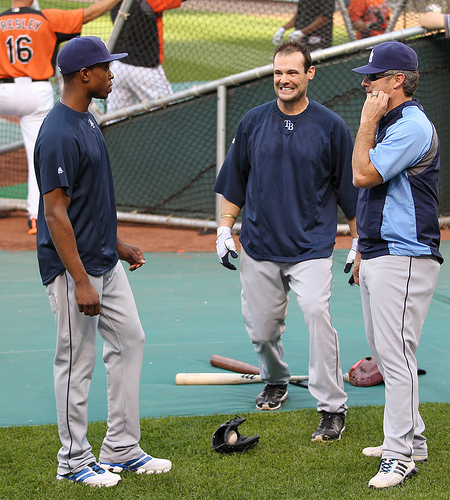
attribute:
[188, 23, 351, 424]
man — smiling, standing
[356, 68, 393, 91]
sunglasses — black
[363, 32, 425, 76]
cap — blue, baseball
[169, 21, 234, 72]
netting — mesh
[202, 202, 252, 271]
gloves — white, black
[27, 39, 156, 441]
player — black, standing, 16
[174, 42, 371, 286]
player — white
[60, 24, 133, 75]
hat — baseball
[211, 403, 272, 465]
mitt — black, leather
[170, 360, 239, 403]
bat — wooden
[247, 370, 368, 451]
shoe — black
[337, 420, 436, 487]
shoes — white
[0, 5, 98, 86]
shirt — orange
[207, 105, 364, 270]
shirt — blue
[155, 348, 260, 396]
floor — artificial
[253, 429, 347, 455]
grass — green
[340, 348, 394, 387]
glove — brown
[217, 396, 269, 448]
glove — black